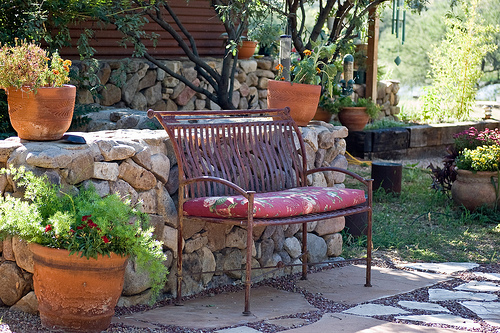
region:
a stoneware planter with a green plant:
[451, 145, 497, 214]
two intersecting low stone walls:
[0, 107, 348, 313]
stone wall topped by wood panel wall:
[0, 1, 283, 136]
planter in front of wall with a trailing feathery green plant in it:
[0, 170, 167, 331]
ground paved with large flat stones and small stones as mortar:
[116, 253, 497, 332]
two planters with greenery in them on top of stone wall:
[3, 31, 340, 161]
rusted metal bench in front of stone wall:
[144, 103, 374, 316]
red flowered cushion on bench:
[182, 185, 369, 225]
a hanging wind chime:
[386, 1, 408, 66]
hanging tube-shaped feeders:
[277, 3, 357, 97]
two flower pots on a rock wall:
[8, 80, 350, 162]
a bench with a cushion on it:
[148, 112, 376, 302]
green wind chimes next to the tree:
[373, 0, 412, 62]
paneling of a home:
[0, 1, 246, 69]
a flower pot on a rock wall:
[196, 36, 271, 89]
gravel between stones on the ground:
[206, 273, 482, 330]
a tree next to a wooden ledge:
[428, 0, 498, 142]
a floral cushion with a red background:
[187, 183, 366, 215]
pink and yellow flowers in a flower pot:
[448, 127, 498, 216]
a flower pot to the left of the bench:
[3, 107, 258, 331]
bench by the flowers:
[147, 101, 404, 315]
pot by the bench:
[2, 160, 137, 330]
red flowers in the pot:
[42, 210, 114, 252]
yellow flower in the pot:
[298, 38, 315, 58]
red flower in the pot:
[100, 232, 110, 245]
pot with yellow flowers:
[268, 33, 324, 120]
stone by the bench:
[116, 159, 159, 194]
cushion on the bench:
[183, 175, 371, 220]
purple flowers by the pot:
[447, 125, 499, 215]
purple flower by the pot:
[464, 125, 472, 133]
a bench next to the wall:
[142, 106, 381, 321]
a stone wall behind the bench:
[27, 123, 349, 286]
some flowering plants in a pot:
[3, 169, 178, 269]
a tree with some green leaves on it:
[81, 4, 271, 111]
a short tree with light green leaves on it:
[428, 24, 480, 117]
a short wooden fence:
[353, 119, 470, 157]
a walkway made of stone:
[166, 260, 498, 332]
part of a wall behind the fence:
[74, 8, 227, 54]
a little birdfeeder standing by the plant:
[276, 32, 293, 78]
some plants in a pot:
[3, 48, 80, 138]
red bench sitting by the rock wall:
[162, 74, 372, 297]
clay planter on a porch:
[28, 168, 173, 325]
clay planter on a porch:
[5, 45, 96, 154]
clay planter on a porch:
[264, 47, 338, 145]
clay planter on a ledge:
[333, 68, 380, 138]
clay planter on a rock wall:
[230, 11, 266, 58]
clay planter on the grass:
[450, 118, 498, 222]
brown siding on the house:
[57, 10, 226, 48]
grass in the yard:
[393, 198, 462, 245]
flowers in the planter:
[271, 40, 338, 78]